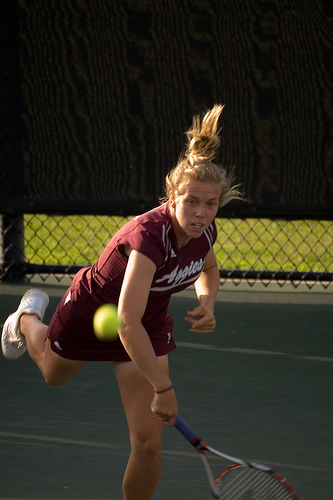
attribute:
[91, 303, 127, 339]
ball — in air, neon green, yellow, moving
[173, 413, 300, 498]
racket — blue orange, whit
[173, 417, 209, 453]
handle — blue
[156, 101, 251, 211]
hair — pony tail, blonde, up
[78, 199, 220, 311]
shirt — maroon, tight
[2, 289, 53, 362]
shoe — white, dirty, whie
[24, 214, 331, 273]
grass — green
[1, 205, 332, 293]
fence — chain link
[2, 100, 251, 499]
woman — tennis player, blonde, grimmacing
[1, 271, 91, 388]
leg — lifted, elevated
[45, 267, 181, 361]
skirt — maroon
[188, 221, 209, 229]
mouth — open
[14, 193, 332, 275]
area — grassy